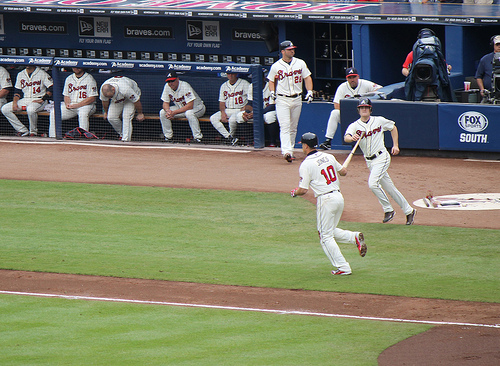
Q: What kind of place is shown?
A: It is a field.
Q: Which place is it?
A: It is a field.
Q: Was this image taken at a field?
A: Yes, it was taken in a field.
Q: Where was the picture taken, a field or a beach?
A: It was taken at a field.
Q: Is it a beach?
A: No, it is a field.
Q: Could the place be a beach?
A: No, it is a field.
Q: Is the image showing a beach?
A: No, the picture is showing a field.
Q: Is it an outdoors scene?
A: Yes, it is outdoors.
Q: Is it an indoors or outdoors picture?
A: It is outdoors.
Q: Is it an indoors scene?
A: No, it is outdoors.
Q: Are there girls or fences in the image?
A: No, there are no fences or girls.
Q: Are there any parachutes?
A: No, there are no parachutes.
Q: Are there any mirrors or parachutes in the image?
A: No, there are no parachutes or mirrors.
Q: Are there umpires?
A: No, there are no umpires.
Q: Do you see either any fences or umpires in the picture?
A: No, there are no umpires or fences.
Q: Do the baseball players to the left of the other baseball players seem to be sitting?
A: Yes, the baseball players are sitting.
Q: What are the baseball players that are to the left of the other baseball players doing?
A: The baseball players are sitting.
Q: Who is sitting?
A: The baseball players are sitting.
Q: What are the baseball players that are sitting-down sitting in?
A: The baseball players are sitting in the dugout.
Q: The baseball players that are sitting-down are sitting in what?
A: The baseball players are sitting in the dugout.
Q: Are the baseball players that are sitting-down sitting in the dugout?
A: Yes, the baseball players are sitting in the dugout.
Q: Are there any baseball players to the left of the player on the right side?
A: Yes, there are baseball players to the left of the player.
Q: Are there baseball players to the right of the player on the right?
A: No, the baseball players are to the left of the player.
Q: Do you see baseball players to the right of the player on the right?
A: No, the baseball players are to the left of the player.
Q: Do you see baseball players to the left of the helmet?
A: Yes, there are baseball players to the left of the helmet.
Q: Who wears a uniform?
A: The player wears a uniform.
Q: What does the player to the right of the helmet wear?
A: The player wears a uniform.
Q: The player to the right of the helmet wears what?
A: The player wears a uniform.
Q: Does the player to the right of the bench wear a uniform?
A: Yes, the player wears a uniform.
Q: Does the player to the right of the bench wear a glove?
A: No, the player wears a uniform.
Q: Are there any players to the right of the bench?
A: Yes, there is a player to the right of the bench.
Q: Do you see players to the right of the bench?
A: Yes, there is a player to the right of the bench.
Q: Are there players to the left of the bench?
A: No, the player is to the right of the bench.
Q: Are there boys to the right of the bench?
A: No, there is a player to the right of the bench.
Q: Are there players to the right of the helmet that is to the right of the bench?
A: Yes, there is a player to the right of the helmet.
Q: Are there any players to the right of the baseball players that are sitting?
A: Yes, there is a player to the right of the baseball players.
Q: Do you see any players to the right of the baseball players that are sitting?
A: Yes, there is a player to the right of the baseball players.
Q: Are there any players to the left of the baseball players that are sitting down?
A: No, the player is to the right of the baseball players.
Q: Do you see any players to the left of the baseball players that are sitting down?
A: No, the player is to the right of the baseball players.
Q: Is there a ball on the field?
A: No, there is a player on the field.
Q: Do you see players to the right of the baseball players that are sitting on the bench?
A: Yes, there is a player to the right of the baseball players.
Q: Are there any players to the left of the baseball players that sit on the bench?
A: No, the player is to the right of the baseball players.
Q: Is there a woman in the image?
A: No, there are no women.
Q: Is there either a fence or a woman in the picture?
A: No, there are no women or fences.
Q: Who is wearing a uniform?
A: The player is wearing a uniform.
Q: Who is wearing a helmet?
A: The player is wearing a helmet.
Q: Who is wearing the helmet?
A: The player is wearing a helmet.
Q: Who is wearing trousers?
A: The player is wearing trousers.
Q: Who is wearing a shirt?
A: The player is wearing a shirt.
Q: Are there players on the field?
A: Yes, there is a player on the field.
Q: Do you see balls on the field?
A: No, there is a player on the field.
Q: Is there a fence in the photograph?
A: No, there are no fences.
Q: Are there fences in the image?
A: No, there are no fences.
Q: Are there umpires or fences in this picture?
A: No, there are no fences or umpires.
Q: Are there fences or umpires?
A: No, there are no fences or umpires.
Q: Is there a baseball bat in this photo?
A: Yes, there is a baseball bat.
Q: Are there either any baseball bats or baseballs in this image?
A: Yes, there is a baseball bat.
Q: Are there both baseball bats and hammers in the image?
A: No, there is a baseball bat but no hammers.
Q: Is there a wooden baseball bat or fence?
A: Yes, there is a wood baseball bat.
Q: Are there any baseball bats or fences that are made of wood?
A: Yes, the baseball bat is made of wood.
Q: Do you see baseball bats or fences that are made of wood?
A: Yes, the baseball bat is made of wood.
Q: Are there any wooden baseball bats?
A: Yes, there is a wood baseball bat.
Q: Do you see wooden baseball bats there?
A: Yes, there is a wood baseball bat.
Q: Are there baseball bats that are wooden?
A: Yes, there is a baseball bat that is wooden.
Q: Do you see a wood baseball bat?
A: Yes, there is a baseball bat that is made of wood.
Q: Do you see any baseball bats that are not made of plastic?
A: Yes, there is a baseball bat that is made of wood.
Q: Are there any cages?
A: No, there are no cages.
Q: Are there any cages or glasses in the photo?
A: No, there are no cages or glasses.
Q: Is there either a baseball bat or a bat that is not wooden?
A: No, there is a baseball bat but it is wooden.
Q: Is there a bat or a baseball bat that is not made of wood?
A: No, there is a baseball bat but it is made of wood.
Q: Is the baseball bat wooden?
A: Yes, the baseball bat is wooden.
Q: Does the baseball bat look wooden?
A: Yes, the baseball bat is wooden.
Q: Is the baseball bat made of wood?
A: Yes, the baseball bat is made of wood.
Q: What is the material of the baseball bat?
A: The baseball bat is made of wood.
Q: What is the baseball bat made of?
A: The baseball bat is made of wood.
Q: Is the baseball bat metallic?
A: No, the baseball bat is wooden.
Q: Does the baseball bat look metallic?
A: No, the baseball bat is wooden.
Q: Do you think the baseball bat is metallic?
A: No, the baseball bat is wooden.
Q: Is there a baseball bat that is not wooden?
A: No, there is a baseball bat but it is wooden.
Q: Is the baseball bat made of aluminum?
A: No, the baseball bat is made of wood.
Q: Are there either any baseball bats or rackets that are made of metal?
A: No, there is a baseball bat but it is made of wood.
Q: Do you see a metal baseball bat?
A: No, there is a baseball bat but it is made of wood.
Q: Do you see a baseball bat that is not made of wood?
A: No, there is a baseball bat but it is made of wood.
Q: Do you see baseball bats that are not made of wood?
A: No, there is a baseball bat but it is made of wood.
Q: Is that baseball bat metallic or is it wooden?
A: The baseball bat is wooden.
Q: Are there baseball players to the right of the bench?
A: Yes, there are baseball players to the right of the bench.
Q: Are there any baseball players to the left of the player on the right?
A: Yes, there are baseball players to the left of the player.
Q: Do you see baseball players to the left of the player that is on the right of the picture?
A: Yes, there are baseball players to the left of the player.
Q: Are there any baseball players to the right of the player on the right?
A: No, the baseball players are to the left of the player.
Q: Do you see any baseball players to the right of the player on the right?
A: No, the baseball players are to the left of the player.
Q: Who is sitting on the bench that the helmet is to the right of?
A: The baseball players are sitting on the bench.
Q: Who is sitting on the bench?
A: The baseball players are sitting on the bench.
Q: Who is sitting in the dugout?
A: The baseball players are sitting in the dugout.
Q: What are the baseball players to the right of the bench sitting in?
A: The baseball players are sitting in the dugout.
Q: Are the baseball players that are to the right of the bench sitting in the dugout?
A: Yes, the baseball players are sitting in the dugout.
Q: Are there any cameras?
A: Yes, there is a camera.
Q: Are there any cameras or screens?
A: Yes, there is a camera.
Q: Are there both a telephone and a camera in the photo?
A: No, there is a camera but no phones.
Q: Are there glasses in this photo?
A: No, there are no glasses.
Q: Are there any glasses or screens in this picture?
A: No, there are no glasses or screens.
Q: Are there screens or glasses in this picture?
A: No, there are no glasses or screens.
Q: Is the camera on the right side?
A: Yes, the camera is on the right of the image.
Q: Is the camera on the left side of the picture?
A: No, the camera is on the right of the image.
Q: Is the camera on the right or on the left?
A: The camera is on the right of the image.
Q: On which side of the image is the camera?
A: The camera is on the right of the image.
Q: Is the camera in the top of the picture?
A: Yes, the camera is in the top of the image.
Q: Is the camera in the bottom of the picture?
A: No, the camera is in the top of the image.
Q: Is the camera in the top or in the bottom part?
A: The camera is in the top of the image.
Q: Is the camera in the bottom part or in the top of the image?
A: The camera is in the top of the image.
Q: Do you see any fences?
A: No, there are no fences.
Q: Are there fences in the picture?
A: No, there are no fences.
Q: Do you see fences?
A: No, there are no fences.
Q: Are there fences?
A: No, there are no fences.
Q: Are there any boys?
A: No, there are no boys.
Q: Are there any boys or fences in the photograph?
A: No, there are no boys or fences.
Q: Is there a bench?
A: Yes, there is a bench.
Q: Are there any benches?
A: Yes, there is a bench.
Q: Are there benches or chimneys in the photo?
A: Yes, there is a bench.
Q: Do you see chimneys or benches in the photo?
A: Yes, there is a bench.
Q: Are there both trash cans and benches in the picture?
A: No, there is a bench but no trash cans.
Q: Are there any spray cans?
A: No, there are no spray cans.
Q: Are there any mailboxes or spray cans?
A: No, there are no spray cans or mailboxes.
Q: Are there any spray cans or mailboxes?
A: No, there are no spray cans or mailboxes.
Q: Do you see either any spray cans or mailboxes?
A: No, there are no spray cans or mailboxes.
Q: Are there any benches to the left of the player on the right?
A: Yes, there is a bench to the left of the player.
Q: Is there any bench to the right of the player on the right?
A: No, the bench is to the left of the player.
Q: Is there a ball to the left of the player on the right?
A: No, there is a bench to the left of the player.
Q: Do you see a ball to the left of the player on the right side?
A: No, there is a bench to the left of the player.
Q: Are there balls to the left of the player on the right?
A: No, there is a bench to the left of the player.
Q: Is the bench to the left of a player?
A: Yes, the bench is to the left of a player.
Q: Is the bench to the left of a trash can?
A: No, the bench is to the left of a player.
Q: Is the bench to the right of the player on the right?
A: No, the bench is to the left of the player.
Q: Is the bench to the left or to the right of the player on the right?
A: The bench is to the left of the player.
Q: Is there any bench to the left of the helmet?
A: Yes, there is a bench to the left of the helmet.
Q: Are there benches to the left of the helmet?
A: Yes, there is a bench to the left of the helmet.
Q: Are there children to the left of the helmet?
A: No, there is a bench to the left of the helmet.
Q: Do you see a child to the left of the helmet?
A: No, there is a bench to the left of the helmet.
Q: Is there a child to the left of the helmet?
A: No, there is a bench to the left of the helmet.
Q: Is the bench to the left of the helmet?
A: Yes, the bench is to the left of the helmet.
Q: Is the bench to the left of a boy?
A: No, the bench is to the left of the helmet.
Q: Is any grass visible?
A: Yes, there is grass.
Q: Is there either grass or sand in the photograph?
A: Yes, there is grass.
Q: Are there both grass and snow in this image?
A: No, there is grass but no snow.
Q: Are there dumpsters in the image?
A: No, there are no dumpsters.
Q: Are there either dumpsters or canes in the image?
A: No, there are no dumpsters or canes.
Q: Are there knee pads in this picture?
A: No, there are no knee pads.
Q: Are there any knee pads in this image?
A: No, there are no knee pads.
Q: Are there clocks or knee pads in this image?
A: No, there are no knee pads or clocks.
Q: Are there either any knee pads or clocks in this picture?
A: No, there are no knee pads or clocks.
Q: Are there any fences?
A: No, there are no fences.